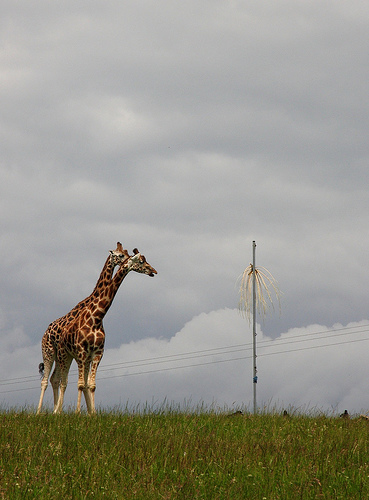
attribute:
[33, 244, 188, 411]
giraffes — standing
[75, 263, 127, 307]
neck — long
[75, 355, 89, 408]
leg — long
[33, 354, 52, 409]
leg — long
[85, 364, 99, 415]
leg — long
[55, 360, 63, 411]
leg — long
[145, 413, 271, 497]
grass — long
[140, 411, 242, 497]
grass — green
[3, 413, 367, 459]
grass — tall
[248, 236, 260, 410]
pole — metal, silver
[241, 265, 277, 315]
hay — brown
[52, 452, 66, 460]
seeds — brown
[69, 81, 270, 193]
sky — overcast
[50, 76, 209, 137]
sky — overcast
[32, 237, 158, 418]
zebras — looking ahead